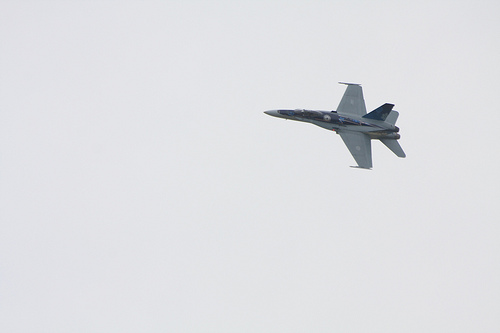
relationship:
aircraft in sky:
[259, 78, 409, 170] [0, 1, 498, 331]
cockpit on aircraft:
[282, 110, 298, 116] [259, 78, 409, 170]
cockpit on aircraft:
[282, 104, 308, 115] [259, 79, 441, 176]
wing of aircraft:
[333, 79, 368, 115] [259, 78, 409, 170]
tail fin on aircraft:
[362, 102, 394, 121] [259, 78, 409, 170]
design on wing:
[355, 143, 362, 152] [368, 97, 401, 129]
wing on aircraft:
[368, 97, 401, 129] [244, 61, 424, 203]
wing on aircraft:
[334, 127, 379, 170] [244, 61, 424, 203]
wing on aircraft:
[330, 76, 360, 109] [244, 61, 424, 203]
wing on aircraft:
[377, 137, 426, 172] [244, 61, 424, 203]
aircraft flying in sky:
[259, 78, 409, 170] [70, 36, 200, 196]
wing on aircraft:
[333, 79, 368, 115] [253, 60, 428, 196]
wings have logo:
[336, 81, 374, 171] [349, 100, 356, 107]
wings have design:
[336, 81, 374, 171] [355, 143, 362, 152]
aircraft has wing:
[259, 78, 409, 170] [342, 139, 381, 176]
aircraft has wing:
[259, 78, 409, 170] [377, 132, 442, 172]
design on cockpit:
[329, 107, 339, 129] [282, 110, 298, 116]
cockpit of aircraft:
[282, 110, 298, 116] [259, 76, 402, 168]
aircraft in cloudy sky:
[259, 78, 409, 170] [0, 1, 500, 330]